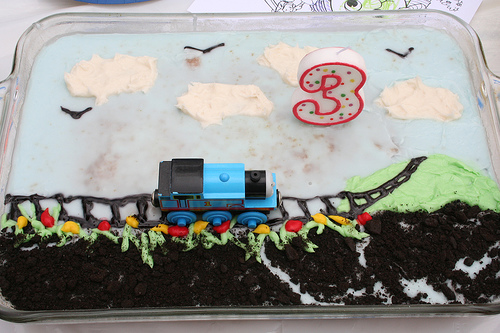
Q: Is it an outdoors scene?
A: Yes, it is outdoors.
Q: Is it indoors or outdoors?
A: It is outdoors.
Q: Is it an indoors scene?
A: No, it is outdoors.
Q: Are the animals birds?
A: Yes, all the animals are birds.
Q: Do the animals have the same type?
A: Yes, all the animals are birds.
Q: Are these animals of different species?
A: No, all the animals are birds.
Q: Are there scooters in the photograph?
A: No, there are no scooters.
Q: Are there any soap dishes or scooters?
A: No, there are no scooters or soap dishes.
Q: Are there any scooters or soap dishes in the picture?
A: No, there are no scooters or soap dishes.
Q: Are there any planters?
A: No, there are no planters.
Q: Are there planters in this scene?
A: No, there are no planters.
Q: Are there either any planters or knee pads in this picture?
A: No, there are no planters or knee pads.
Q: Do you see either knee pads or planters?
A: No, there are no planters or knee pads.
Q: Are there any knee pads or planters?
A: No, there are no planters or knee pads.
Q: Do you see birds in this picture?
A: Yes, there is a bird.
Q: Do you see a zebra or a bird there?
A: Yes, there is a bird.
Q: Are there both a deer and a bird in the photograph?
A: No, there is a bird but no deer.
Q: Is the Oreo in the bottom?
A: Yes, the Oreo is in the bottom of the image.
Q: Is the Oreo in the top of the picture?
A: No, the Oreo is in the bottom of the image.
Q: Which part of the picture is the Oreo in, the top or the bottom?
A: The Oreo is in the bottom of the image.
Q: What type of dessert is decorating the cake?
A: The dessert is Oreo.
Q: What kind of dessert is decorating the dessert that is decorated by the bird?
A: The dessert is Oreo.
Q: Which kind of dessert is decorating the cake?
A: The dessert is Oreo.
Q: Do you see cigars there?
A: No, there are no cigars.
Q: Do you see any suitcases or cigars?
A: No, there are no cigars or suitcases.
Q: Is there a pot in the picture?
A: No, there are no pots.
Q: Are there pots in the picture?
A: No, there are no pots.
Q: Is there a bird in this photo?
A: Yes, there is a bird.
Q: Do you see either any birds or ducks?
A: Yes, there is a bird.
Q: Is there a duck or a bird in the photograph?
A: Yes, there is a bird.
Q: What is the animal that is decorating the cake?
A: The animal is a bird.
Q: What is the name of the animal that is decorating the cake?
A: The animal is a bird.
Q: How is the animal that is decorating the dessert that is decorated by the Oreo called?
A: The animal is a bird.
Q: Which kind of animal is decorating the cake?
A: The animal is a bird.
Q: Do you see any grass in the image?
A: Yes, there is grass.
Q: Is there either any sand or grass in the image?
A: Yes, there is grass.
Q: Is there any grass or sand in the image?
A: Yes, there is grass.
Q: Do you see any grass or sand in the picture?
A: Yes, there is grass.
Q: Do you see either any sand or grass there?
A: Yes, there is grass.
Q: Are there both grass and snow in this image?
A: No, there is grass but no snow.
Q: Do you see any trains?
A: Yes, there is a train.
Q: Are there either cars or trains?
A: Yes, there is a train.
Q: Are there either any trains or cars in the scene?
A: Yes, there is a train.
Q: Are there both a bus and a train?
A: No, there is a train but no buses.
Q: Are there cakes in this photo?
A: Yes, there is a cake.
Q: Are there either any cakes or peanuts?
A: Yes, there is a cake.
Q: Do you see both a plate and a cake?
A: No, there is a cake but no plates.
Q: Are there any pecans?
A: No, there are no pecans.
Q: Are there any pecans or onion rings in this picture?
A: No, there are no pecans or onion rings.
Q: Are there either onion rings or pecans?
A: No, there are no pecans or onion rings.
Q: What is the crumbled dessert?
A: The dessert is a cake.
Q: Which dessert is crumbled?
A: The dessert is a cake.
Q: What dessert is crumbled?
A: The dessert is a cake.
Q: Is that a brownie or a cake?
A: That is a cake.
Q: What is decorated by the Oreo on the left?
A: The cake is decorated by the Oreo.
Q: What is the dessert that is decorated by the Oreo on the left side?
A: The dessert is a cake.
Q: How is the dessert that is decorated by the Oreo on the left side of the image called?
A: The dessert is a cake.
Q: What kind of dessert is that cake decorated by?
A: The cake is decorated by the Oreo.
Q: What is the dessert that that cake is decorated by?
A: The dessert is Oreo.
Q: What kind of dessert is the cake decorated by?
A: The cake is decorated by the Oreo.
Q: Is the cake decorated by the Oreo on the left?
A: Yes, the cake is decorated by the Oreo.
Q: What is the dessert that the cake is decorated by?
A: The dessert is Oreo.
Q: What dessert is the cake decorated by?
A: The cake is decorated by the Oreo.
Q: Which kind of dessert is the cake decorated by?
A: The cake is decorated by the Oreo.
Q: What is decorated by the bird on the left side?
A: The cake is decorated by the bird.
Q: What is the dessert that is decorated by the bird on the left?
A: The dessert is a cake.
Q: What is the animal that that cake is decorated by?
A: The animal is a bird.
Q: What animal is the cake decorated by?
A: The cake is decorated by the bird.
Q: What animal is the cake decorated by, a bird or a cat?
A: The cake is decorated by a bird.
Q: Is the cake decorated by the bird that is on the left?
A: Yes, the cake is decorated by the bird.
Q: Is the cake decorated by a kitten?
A: No, the cake is decorated by the bird.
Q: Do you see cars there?
A: No, there are no cars.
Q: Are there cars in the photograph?
A: No, there are no cars.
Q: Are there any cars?
A: No, there are no cars.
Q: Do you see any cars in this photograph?
A: No, there are no cars.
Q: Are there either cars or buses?
A: No, there are no cars or buses.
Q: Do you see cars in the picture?
A: No, there are no cars.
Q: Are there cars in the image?
A: No, there are no cars.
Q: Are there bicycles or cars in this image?
A: No, there are no cars or bicycles.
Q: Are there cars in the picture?
A: No, there are no cars.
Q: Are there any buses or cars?
A: No, there are no cars or buses.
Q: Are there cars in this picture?
A: No, there are no cars.